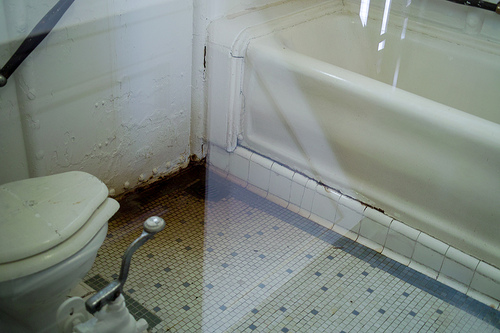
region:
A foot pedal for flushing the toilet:
[54, 213, 175, 332]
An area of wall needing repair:
[48, 20, 232, 234]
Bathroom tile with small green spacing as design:
[68, 164, 494, 331]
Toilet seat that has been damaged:
[1, 134, 121, 329]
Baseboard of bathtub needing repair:
[196, 127, 400, 265]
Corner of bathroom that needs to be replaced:
[11, 15, 392, 292]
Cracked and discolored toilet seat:
[1, 159, 121, 287]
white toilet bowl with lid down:
[5, 156, 108, 331]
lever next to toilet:
[88, 209, 169, 314]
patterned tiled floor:
[109, 194, 499, 324]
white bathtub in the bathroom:
[229, 19, 499, 275]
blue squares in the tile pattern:
[104, 199, 476, 331]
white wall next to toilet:
[7, 2, 182, 194]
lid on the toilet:
[3, 163, 109, 266]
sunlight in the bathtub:
[358, 0, 420, 88]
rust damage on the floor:
[110, 153, 292, 247]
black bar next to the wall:
[3, 2, 63, 88]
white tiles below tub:
[213, 144, 498, 308]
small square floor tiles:
[85, 176, 495, 331]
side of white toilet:
[0, 171, 120, 332]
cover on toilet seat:
[0, 169, 117, 277]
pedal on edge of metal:
[88, 214, 163, 311]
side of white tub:
[241, 41, 498, 268]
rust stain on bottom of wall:
[117, 153, 206, 213]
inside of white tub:
[303, 23, 498, 127]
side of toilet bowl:
[0, 225, 109, 331]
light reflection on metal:
[125, 230, 146, 254]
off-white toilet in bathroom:
[0, 170, 122, 323]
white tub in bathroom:
[204, 2, 499, 309]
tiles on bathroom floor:
[70, 177, 497, 331]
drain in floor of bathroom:
[187, 174, 230, 201]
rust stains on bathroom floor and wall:
[110, 155, 316, 240]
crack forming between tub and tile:
[235, 139, 391, 217]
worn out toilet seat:
[0, 168, 121, 280]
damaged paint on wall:
[24, 83, 199, 195]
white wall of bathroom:
[2, 2, 201, 198]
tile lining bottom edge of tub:
[205, 140, 499, 310]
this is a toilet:
[2, 171, 121, 311]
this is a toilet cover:
[4, 173, 112, 265]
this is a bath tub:
[226, 21, 496, 313]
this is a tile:
[441, 249, 474, 294]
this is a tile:
[359, 204, 391, 252]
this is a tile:
[334, 190, 367, 235]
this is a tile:
[262, 156, 288, 198]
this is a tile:
[432, 246, 480, 296]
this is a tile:
[209, 139, 249, 181]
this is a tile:
[269, 159, 291, 202]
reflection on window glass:
[3, 1, 498, 328]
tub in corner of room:
[239, 1, 499, 265]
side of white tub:
[247, 47, 499, 264]